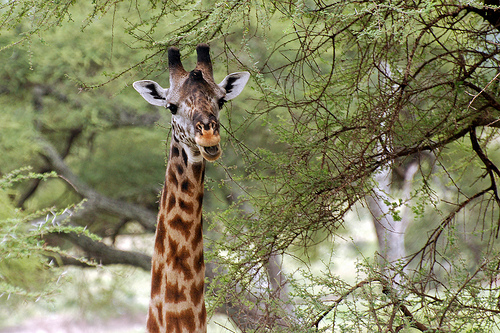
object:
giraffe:
[133, 44, 250, 333]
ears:
[130, 79, 168, 105]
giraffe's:
[132, 71, 256, 160]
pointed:
[238, 69, 251, 81]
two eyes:
[165, 96, 225, 115]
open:
[198, 145, 221, 160]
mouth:
[197, 144, 225, 160]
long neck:
[146, 162, 210, 332]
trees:
[363, 47, 427, 332]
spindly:
[261, 37, 294, 70]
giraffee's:
[192, 138, 223, 166]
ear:
[218, 71, 251, 101]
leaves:
[254, 74, 265, 79]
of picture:
[441, 11, 499, 66]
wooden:
[67, 181, 90, 193]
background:
[97, 103, 121, 130]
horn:
[164, 46, 187, 75]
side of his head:
[161, 82, 195, 145]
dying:
[227, 166, 236, 172]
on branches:
[343, 91, 426, 168]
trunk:
[57, 212, 94, 251]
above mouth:
[192, 118, 221, 146]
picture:
[0, 0, 500, 333]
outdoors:
[0, 0, 494, 333]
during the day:
[0, 0, 500, 333]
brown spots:
[164, 193, 175, 214]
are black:
[149, 86, 154, 89]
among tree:
[361, 32, 469, 123]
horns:
[196, 42, 211, 74]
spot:
[167, 214, 194, 241]